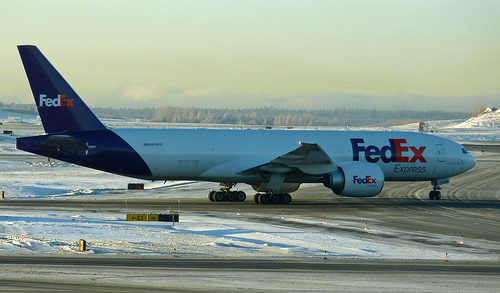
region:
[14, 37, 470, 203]
large white plane on tarmac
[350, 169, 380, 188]
logo on side of plane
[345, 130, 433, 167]
logo on side of plane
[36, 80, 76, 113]
logo on side of plane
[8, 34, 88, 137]
large blue tail fin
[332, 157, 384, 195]
white jet engine on plane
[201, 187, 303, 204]
back wheels on plane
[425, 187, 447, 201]
front wheels on plane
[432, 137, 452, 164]
front door of plane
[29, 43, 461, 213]
plane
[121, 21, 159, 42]
white clouds in blue sky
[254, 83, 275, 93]
white clouds in blue sky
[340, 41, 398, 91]
white clouds in blue sky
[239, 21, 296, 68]
white clouds in blue sky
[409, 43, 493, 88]
white clouds in blue sky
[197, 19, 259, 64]
white clouds in blue sky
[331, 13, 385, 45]
white clouds in blue sky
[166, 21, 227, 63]
white clouds in blue sky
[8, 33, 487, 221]
A fedex airplane on a snowy runway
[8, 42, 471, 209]
A large airplane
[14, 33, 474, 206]
An airplane for shipping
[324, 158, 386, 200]
A jet on an airplane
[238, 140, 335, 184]
A wing of an airplane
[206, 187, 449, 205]
The wheels on the bottom of the plane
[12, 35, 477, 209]
A Fed Ex airplane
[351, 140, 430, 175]
Logo on an airplaine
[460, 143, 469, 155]
Window on an airplane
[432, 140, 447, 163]
Door on an airplane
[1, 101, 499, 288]
Snowy landscape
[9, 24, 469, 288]
this is an airplane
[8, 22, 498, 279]
the airplane is parked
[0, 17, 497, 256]
the airplane is on the tarmac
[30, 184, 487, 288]
snow on the tarmac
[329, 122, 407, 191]
purple writing on the plane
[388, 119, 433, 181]
orange writing on plane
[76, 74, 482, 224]
white body of plane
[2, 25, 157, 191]
purple tail on plane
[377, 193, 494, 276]
snow tracks on tarmac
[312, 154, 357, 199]
silver engine part on plane